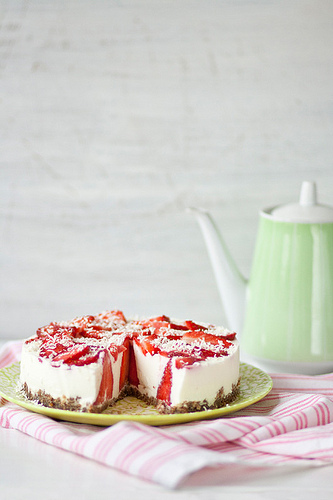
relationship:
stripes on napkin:
[263, 416, 284, 435] [2, 368, 332, 492]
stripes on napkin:
[289, 413, 302, 433] [2, 368, 332, 492]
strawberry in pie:
[155, 360, 174, 404] [18, 308, 247, 415]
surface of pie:
[191, 366, 228, 398] [18, 308, 247, 415]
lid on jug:
[261, 170, 331, 228] [177, 198, 331, 385]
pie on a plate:
[18, 308, 247, 415] [0, 328, 258, 421]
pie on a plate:
[18, 308, 247, 415] [0, 358, 272, 425]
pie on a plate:
[18, 308, 247, 415] [1, 327, 275, 430]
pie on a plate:
[18, 308, 247, 415] [4, 350, 276, 423]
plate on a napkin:
[0, 358, 272, 425] [0, 336, 333, 487]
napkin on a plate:
[2, 368, 332, 492] [0, 358, 272, 425]